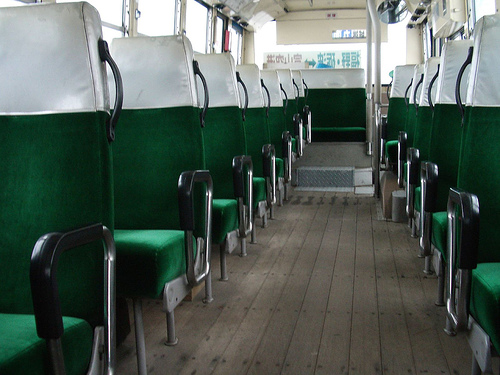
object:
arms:
[173, 171, 213, 268]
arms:
[433, 187, 480, 332]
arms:
[405, 157, 436, 249]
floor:
[276, 230, 408, 339]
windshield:
[258, 19, 400, 74]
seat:
[409, 57, 441, 237]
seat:
[274, 65, 311, 157]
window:
[189, 6, 217, 53]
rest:
[171, 191, 252, 292]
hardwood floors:
[284, 214, 419, 367]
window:
[136, 0, 184, 30]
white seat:
[98, 24, 229, 251]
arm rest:
[29, 215, 106, 336]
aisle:
[167, 127, 465, 369]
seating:
[3, 2, 119, 374]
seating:
[110, 31, 206, 323]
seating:
[194, 47, 256, 275]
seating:
[240, 61, 283, 234]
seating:
[448, 14, 498, 371]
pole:
[358, 11, 402, 174]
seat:
[4, 3, 147, 373]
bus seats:
[381, 15, 499, 369]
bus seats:
[0, 1, 314, 372]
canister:
[390, 185, 410, 225]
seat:
[387, 16, 495, 307]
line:
[211, 264, 443, 284]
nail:
[344, 307, 352, 315]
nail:
[300, 305, 310, 315]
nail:
[396, 310, 404, 318]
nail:
[407, 310, 415, 317]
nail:
[375, 272, 382, 282]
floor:
[182, 288, 477, 371]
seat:
[68, 5, 238, 356]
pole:
[258, 208, 272, 231]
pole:
[202, 275, 213, 302]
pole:
[220, 255, 228, 280]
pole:
[163, 312, 176, 341]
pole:
[240, 236, 248, 255]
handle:
[89, 35, 134, 144]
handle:
[185, 57, 216, 129]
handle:
[232, 70, 254, 121]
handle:
[450, 45, 480, 122]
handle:
[424, 60, 442, 120]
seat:
[0, 304, 100, 369]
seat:
[204, 192, 240, 241]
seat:
[464, 259, 499, 324]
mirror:
[377, 2, 420, 28]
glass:
[296, 38, 397, 98]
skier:
[95, 37, 128, 138]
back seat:
[109, 31, 199, 133]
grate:
[301, 160, 361, 190]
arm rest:
[261, 140, 276, 206]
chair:
[444, 13, 499, 373]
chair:
[108, 35, 210, 373]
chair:
[195, 51, 253, 280]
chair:
[235, 60, 275, 230]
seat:
[326, 97, 361, 123]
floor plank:
[261, 152, 417, 370]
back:
[308, 65, 362, 125]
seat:
[420, 32, 477, 294]